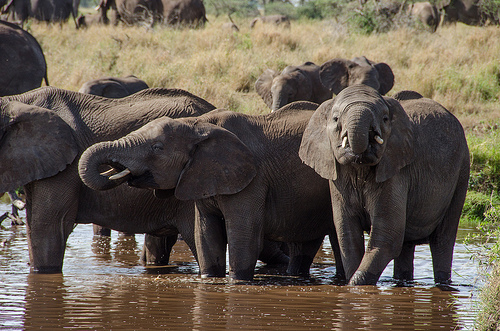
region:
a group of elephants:
[6, 38, 498, 312]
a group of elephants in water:
[10, 25, 444, 297]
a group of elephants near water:
[4, 23, 495, 295]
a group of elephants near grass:
[11, 20, 480, 309]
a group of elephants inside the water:
[19, 18, 488, 255]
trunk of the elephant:
[57, 113, 154, 214]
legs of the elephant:
[327, 198, 426, 266]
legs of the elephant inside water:
[316, 252, 412, 304]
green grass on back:
[268, 31, 494, 82]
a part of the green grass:
[456, 108, 498, 238]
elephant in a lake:
[305, 86, 471, 292]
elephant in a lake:
[83, 115, 284, 276]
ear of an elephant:
[2, 95, 77, 177]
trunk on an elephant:
[80, 130, 155, 190]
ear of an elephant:
[171, 127, 259, 207]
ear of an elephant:
[286, 102, 326, 173]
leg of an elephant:
[355, 190, 396, 300]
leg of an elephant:
[322, 187, 357, 267]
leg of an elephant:
[215, 202, 266, 293]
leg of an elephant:
[191, 219, 219, 281]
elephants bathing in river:
[0, 52, 480, 302]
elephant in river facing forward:
[291, 88, 471, 289]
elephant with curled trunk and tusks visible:
[80, 120, 293, 280]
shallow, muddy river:
[76, 270, 247, 329]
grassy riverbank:
[148, 23, 495, 77]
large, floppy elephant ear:
[182, 123, 259, 206]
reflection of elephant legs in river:
[391, 269, 463, 326]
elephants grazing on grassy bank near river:
[44, 2, 219, 39]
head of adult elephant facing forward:
[300, 86, 420, 185]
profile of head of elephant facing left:
[75, 114, 257, 206]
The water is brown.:
[1, 275, 493, 329]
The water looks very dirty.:
[2, 278, 482, 329]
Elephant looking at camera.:
[297, 84, 470, 292]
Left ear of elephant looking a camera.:
[299, 98, 338, 180]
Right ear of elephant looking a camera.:
[376, 95, 418, 178]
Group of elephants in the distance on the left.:
[3, 2, 208, 27]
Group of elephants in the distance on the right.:
[351, 2, 498, 29]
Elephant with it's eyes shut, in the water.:
[79, 99, 344, 282]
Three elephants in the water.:
[0, 85, 469, 284]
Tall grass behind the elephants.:
[53, 28, 498, 107]